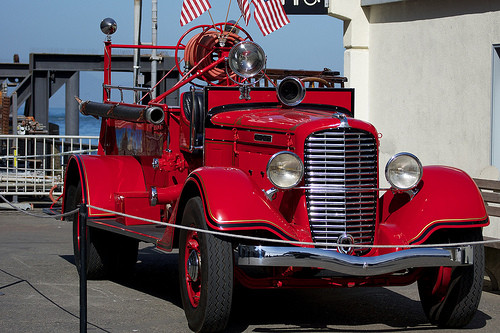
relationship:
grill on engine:
[297, 125, 376, 261] [160, 10, 249, 81]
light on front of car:
[266, 148, 306, 188] [42, 21, 489, 333]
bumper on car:
[223, 226, 490, 289] [42, 21, 489, 333]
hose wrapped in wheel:
[182, 29, 248, 81] [173, 20, 253, 87]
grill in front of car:
[303, 127, 378, 257] [60, 17, 490, 330]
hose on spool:
[183, 30, 235, 79] [174, 21, 254, 87]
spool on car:
[174, 21, 254, 87] [42, 21, 489, 333]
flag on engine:
[175, 0, 216, 30] [48, 16, 498, 328]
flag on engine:
[232, 0, 253, 29] [48, 16, 498, 328]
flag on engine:
[247, 0, 295, 45] [48, 16, 498, 328]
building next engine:
[321, 0, 498, 287] [48, 16, 498, 328]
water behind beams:
[40, 97, 110, 151] [2, 49, 342, 166]